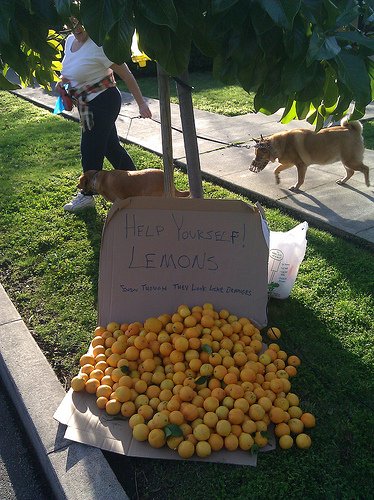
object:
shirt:
[60, 79, 126, 133]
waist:
[62, 83, 133, 110]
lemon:
[239, 365, 258, 387]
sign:
[103, 200, 264, 331]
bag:
[50, 82, 71, 111]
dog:
[248, 121, 370, 191]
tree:
[2, 1, 373, 132]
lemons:
[67, 371, 88, 395]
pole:
[171, 52, 209, 199]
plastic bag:
[266, 219, 308, 301]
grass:
[0, 167, 43, 215]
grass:
[332, 358, 370, 488]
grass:
[200, 67, 254, 107]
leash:
[100, 106, 144, 171]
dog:
[75, 168, 195, 210]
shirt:
[54, 33, 126, 104]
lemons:
[213, 417, 231, 440]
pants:
[79, 86, 138, 173]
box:
[98, 192, 266, 326]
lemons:
[112, 384, 134, 402]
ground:
[0, 47, 373, 500]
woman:
[53, 18, 151, 215]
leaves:
[157, 412, 186, 443]